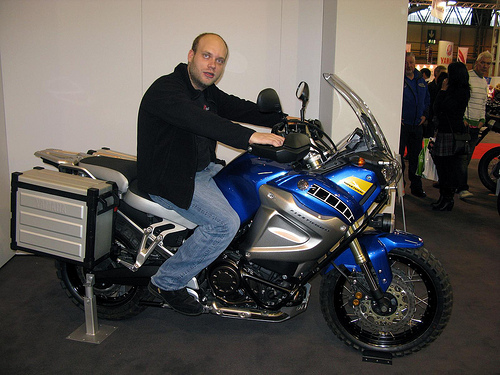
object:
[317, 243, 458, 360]
wheel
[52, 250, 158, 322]
wheel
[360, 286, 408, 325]
chrome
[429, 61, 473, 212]
guest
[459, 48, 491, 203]
guest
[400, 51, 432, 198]
guest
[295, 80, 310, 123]
mirror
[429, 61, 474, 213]
crowd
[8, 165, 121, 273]
box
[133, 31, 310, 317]
biker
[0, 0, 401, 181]
wall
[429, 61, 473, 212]
woman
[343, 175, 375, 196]
yellow box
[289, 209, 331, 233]
black writing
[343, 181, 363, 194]
black writing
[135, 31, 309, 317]
man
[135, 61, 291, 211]
jacket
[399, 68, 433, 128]
jacket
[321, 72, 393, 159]
windshield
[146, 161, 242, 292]
jeans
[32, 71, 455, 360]
motorcycle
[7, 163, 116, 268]
cases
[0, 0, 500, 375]
exhibition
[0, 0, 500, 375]
show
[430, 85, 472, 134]
clothing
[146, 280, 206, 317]
shoe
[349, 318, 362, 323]
spokes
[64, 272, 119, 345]
stand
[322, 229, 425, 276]
fender